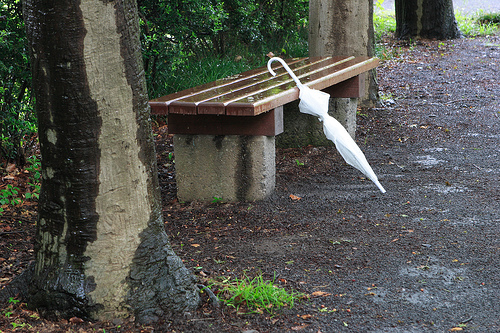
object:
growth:
[209, 196, 221, 205]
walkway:
[180, 38, 499, 331]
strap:
[318, 113, 332, 122]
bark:
[18, 0, 201, 324]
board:
[144, 53, 381, 118]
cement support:
[272, 98, 360, 151]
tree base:
[0, 249, 238, 332]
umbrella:
[260, 55, 389, 196]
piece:
[151, 110, 282, 136]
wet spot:
[0, 3, 112, 333]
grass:
[128, 0, 310, 100]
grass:
[207, 272, 294, 314]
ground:
[154, 25, 500, 331]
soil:
[350, 28, 498, 333]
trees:
[302, 0, 380, 130]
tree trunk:
[10, 0, 200, 321]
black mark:
[115, 7, 176, 314]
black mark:
[30, 7, 96, 307]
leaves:
[301, 313, 312, 320]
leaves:
[378, 92, 395, 104]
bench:
[144, 48, 384, 205]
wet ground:
[0, 40, 497, 333]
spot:
[368, 255, 490, 313]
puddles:
[390, 139, 480, 318]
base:
[167, 112, 276, 205]